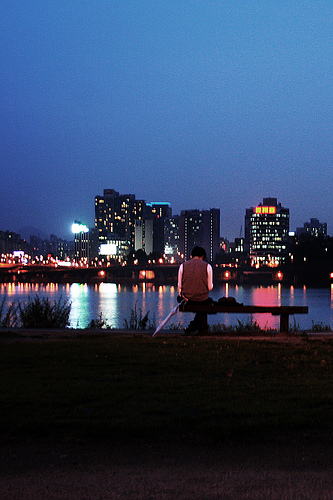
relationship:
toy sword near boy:
[151, 297, 183, 337] [174, 244, 213, 334]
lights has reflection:
[2, 198, 332, 280] [2, 280, 329, 328]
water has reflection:
[0, 281, 332, 329] [2, 280, 329, 328]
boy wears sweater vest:
[176, 248, 214, 333] [180, 258, 207, 299]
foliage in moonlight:
[6, 294, 71, 328] [1, 3, 332, 187]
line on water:
[91, 278, 128, 329] [1, 265, 329, 335]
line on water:
[61, 270, 93, 331] [1, 265, 329, 335]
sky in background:
[9, 69, 332, 189] [6, 9, 328, 244]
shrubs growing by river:
[0, 293, 75, 329] [0, 282, 329, 330]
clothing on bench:
[210, 294, 244, 306] [177, 298, 307, 331]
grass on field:
[50, 360, 216, 428] [2, 340, 330, 497]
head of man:
[190, 242, 207, 258] [177, 250, 215, 298]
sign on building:
[69, 218, 90, 234] [64, 197, 253, 282]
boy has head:
[176, 248, 214, 333] [183, 241, 224, 262]